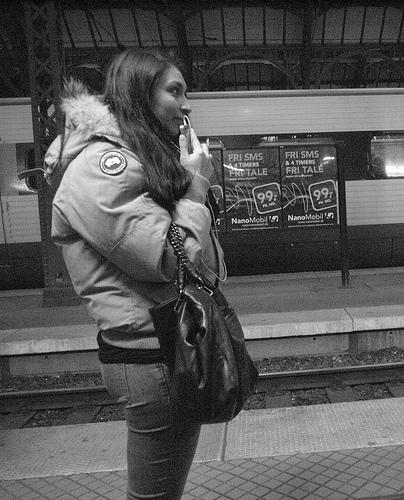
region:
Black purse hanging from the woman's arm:
[152, 220, 264, 426]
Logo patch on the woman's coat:
[89, 147, 130, 183]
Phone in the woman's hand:
[177, 113, 220, 186]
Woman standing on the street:
[43, 45, 262, 496]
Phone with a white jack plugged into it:
[176, 112, 200, 155]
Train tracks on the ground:
[239, 357, 401, 412]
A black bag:
[147, 219, 267, 429]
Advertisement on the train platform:
[220, 147, 342, 228]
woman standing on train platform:
[39, 41, 268, 494]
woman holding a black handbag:
[25, 38, 270, 498]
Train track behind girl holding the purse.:
[0, 363, 403, 409]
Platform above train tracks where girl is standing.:
[1, 399, 401, 498]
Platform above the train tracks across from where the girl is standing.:
[3, 273, 402, 380]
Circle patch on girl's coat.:
[92, 149, 133, 177]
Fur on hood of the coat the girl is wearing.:
[55, 83, 117, 135]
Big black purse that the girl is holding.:
[137, 222, 267, 422]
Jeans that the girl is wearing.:
[103, 362, 198, 498]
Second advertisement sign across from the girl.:
[281, 147, 346, 226]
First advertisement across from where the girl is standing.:
[225, 148, 284, 227]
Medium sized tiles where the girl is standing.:
[0, 445, 403, 499]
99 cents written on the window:
[308, 177, 338, 212]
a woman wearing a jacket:
[44, 61, 220, 359]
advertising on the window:
[221, 151, 279, 231]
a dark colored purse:
[164, 222, 265, 423]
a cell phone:
[176, 122, 199, 155]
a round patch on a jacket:
[97, 148, 130, 180]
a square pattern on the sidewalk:
[26, 450, 403, 499]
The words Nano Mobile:
[286, 210, 325, 221]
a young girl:
[82, 45, 211, 162]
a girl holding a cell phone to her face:
[73, 45, 209, 166]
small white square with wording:
[251, 181, 285, 217]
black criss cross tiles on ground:
[282, 462, 364, 492]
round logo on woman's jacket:
[96, 150, 131, 181]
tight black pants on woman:
[101, 359, 213, 486]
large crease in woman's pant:
[124, 424, 176, 436]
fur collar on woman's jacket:
[39, 84, 137, 156]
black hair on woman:
[98, 50, 204, 182]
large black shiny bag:
[154, 272, 285, 426]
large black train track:
[294, 358, 399, 389]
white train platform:
[279, 292, 382, 353]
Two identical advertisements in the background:
[223, 147, 345, 232]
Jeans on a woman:
[94, 331, 206, 498]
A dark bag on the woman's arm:
[144, 211, 272, 450]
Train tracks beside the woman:
[0, 328, 403, 440]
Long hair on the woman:
[98, 51, 196, 212]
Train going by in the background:
[0, 81, 402, 272]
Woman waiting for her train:
[38, 41, 255, 495]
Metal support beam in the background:
[27, 6, 85, 310]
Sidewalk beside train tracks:
[10, 395, 401, 498]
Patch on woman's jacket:
[97, 141, 128, 180]